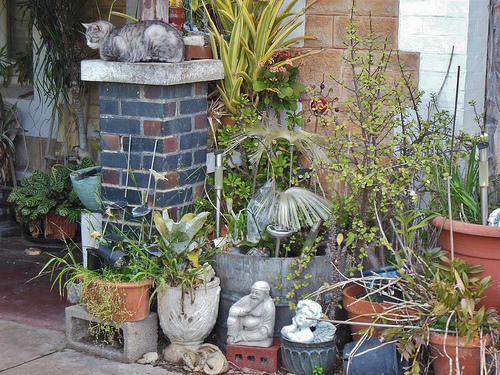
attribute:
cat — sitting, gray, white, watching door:
[82, 13, 182, 73]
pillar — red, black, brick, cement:
[87, 66, 217, 240]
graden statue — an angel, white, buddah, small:
[234, 289, 276, 344]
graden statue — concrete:
[284, 298, 353, 348]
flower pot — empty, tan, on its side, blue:
[350, 337, 412, 370]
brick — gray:
[232, 347, 282, 370]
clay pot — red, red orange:
[47, 205, 73, 249]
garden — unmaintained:
[225, 23, 492, 370]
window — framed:
[1, 12, 43, 101]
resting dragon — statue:
[175, 346, 231, 371]